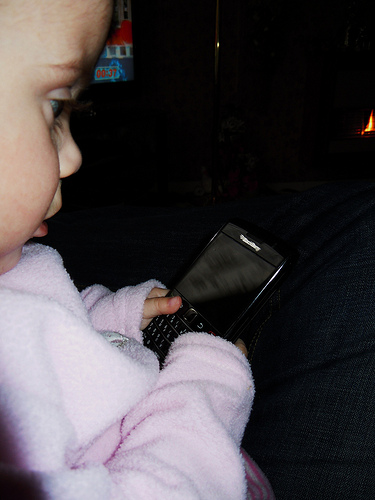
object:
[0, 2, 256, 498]
baby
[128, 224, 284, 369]
blackberry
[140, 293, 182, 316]
thumb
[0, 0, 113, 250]
face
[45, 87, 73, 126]
eye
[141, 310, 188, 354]
keyboard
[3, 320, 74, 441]
fabric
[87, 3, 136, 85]
tv screen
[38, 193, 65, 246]
lips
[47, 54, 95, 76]
eyebrow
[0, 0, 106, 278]
head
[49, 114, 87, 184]
nose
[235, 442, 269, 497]
bottoms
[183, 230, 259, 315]
screen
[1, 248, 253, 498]
clothes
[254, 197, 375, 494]
blue jeans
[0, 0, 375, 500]
shot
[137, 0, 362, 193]
back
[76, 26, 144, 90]
television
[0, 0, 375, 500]
room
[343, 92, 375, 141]
fireplace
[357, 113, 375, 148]
fire